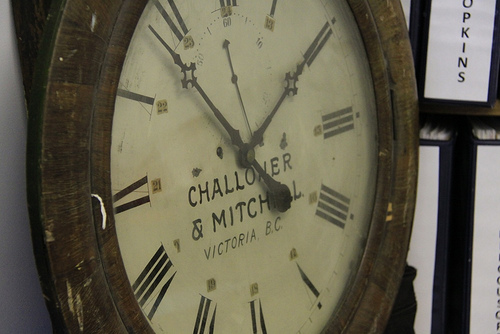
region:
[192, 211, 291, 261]
the word Victoria B.C. on a clock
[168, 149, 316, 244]
the words Challoner and Mitchell on a clock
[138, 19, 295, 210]
the hand of an old clock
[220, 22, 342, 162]
the hand of an old clock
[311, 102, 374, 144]
the roman numeral for 3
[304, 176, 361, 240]
the roman numeral for four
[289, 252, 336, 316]
the roman numeral for five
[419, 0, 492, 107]
a sign with the word opkins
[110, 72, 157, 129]
the roman numeral for 10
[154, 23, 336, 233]
clock's hands are black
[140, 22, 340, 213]
clock's hands are black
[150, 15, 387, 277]
clock's hands are black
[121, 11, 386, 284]
clock's hands are black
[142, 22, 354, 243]
clock's hands are black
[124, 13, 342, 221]
the clock shows 1:54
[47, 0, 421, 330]
old clock with wooden frame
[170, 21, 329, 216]
clock with black hands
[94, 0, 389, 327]
clock with black roman numerals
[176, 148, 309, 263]
clock maker and location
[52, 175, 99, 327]
distressed area of wood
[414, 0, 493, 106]
white paper on side of binder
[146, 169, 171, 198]
numbers indicating military time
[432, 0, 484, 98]
black lettering on binders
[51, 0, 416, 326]
this is a clock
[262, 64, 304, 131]
the hour hand of the clock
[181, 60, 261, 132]
the minute hand of the clock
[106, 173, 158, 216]
this is a number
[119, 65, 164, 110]
this is a roman number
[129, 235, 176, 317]
this is a roman number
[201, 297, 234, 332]
this is a roman number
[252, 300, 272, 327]
this is a roman number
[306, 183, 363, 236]
this is a roman number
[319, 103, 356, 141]
this is a roman number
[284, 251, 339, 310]
a number on the clock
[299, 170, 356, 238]
a number on the clock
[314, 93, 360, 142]
a number on the clock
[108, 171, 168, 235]
a number on the clock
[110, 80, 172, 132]
a number on the clock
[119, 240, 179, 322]
a number on the clock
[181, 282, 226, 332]
a number on the clock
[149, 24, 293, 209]
a clock minute hand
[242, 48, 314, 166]
a clock hour hand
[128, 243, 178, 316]
roman numeral number 8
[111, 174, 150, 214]
roman numeral number 9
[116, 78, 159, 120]
roman numeral number 10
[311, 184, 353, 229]
roman numeral number 4